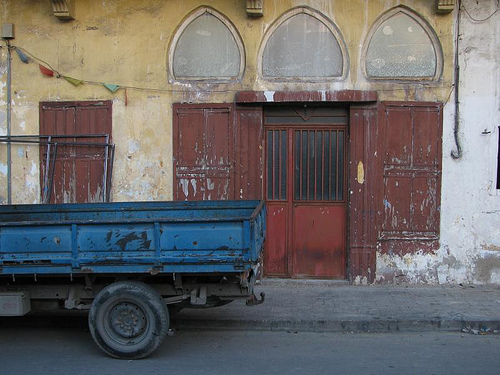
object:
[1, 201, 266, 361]
cart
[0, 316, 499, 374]
road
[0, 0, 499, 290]
wall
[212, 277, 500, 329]
sidewalk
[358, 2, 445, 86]
window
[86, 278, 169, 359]
tire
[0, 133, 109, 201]
fencing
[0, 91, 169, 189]
building siding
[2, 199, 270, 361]
pickup truck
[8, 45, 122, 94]
flags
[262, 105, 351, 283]
door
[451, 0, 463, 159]
hook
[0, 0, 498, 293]
paint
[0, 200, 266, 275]
bed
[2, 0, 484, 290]
building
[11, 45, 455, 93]
line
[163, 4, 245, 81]
window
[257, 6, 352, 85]
window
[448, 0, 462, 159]
electric line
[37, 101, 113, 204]
door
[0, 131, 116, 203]
frame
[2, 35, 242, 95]
banner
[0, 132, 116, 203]
poles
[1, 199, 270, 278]
metal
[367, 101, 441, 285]
door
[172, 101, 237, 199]
door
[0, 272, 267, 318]
chassis